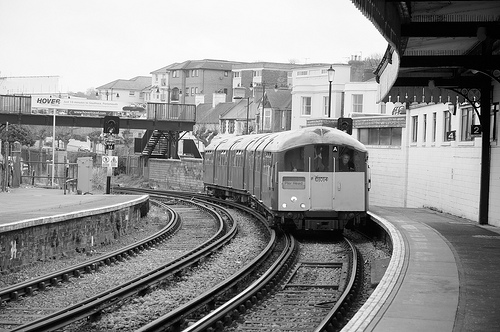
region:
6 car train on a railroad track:
[198, 115, 411, 236]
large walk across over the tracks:
[0, 98, 214, 175]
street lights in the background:
[231, 55, 373, 144]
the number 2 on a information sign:
[464, 110, 486, 149]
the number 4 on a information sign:
[434, 119, 471, 153]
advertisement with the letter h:
[21, 85, 140, 126]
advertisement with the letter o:
[29, 87, 141, 122]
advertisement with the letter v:
[19, 80, 116, 142]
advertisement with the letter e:
[20, 91, 145, 126]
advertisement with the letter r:
[19, 90, 140, 123]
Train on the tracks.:
[171, 97, 454, 278]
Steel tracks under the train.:
[166, 228, 436, 330]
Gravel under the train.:
[216, 186, 363, 324]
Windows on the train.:
[213, 124, 404, 242]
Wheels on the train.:
[263, 195, 380, 272]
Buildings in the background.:
[41, 88, 158, 192]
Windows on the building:
[118, 44, 238, 102]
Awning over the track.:
[366, 36, 499, 141]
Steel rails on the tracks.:
[97, 182, 394, 331]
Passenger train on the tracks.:
[196, 113, 453, 250]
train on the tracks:
[189, 123, 384, 238]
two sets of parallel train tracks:
[1, 156, 389, 330]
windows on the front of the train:
[282, 141, 365, 174]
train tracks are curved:
[134, 181, 348, 265]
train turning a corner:
[177, 108, 399, 270]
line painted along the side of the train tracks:
[336, 201, 414, 330]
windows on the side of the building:
[407, 109, 485, 149]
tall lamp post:
[325, 63, 339, 112]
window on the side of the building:
[294, 91, 311, 119]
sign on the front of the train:
[280, 169, 312, 194]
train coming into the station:
[201, 124, 369, 226]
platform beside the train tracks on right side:
[373, 204, 498, 331]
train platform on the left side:
[7, 171, 151, 268]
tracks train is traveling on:
[190, 219, 367, 329]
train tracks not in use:
[3, 175, 228, 330]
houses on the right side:
[104, 46, 478, 137]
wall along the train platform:
[369, 137, 499, 220]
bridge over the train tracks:
[7, 84, 200, 134]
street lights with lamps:
[235, 62, 339, 127]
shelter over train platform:
[358, 1, 492, 106]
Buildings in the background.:
[99, 40, 398, 228]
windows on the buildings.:
[117, 20, 235, 120]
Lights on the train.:
[249, 124, 359, 214]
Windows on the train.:
[230, 132, 293, 188]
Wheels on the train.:
[271, 202, 354, 234]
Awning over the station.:
[366, 29, 445, 97]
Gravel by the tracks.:
[113, 190, 273, 315]